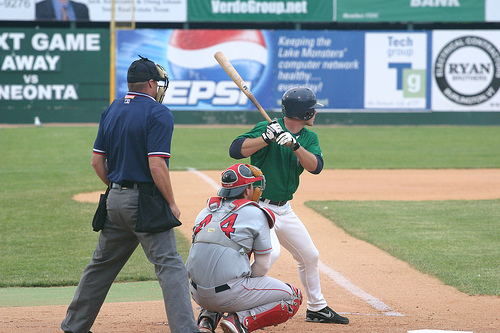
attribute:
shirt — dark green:
[265, 149, 296, 191]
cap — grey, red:
[217, 161, 263, 200]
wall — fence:
[0, 19, 498, 124]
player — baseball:
[212, 51, 349, 324]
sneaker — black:
[302, 301, 354, 327]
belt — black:
[180, 261, 258, 298]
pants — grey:
[103, 190, 173, 331]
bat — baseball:
[212, 54, 276, 138]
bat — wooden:
[196, 45, 286, 135]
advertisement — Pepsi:
[122, 28, 371, 117]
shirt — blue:
[91, 91, 174, 182]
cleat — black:
[305, 305, 349, 324]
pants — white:
[246, 200, 328, 317]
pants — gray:
[44, 185, 201, 331]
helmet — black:
[279, 85, 325, 120]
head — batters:
[280, 85, 325, 130]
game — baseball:
[10, 12, 485, 285]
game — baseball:
[55, 32, 429, 296]